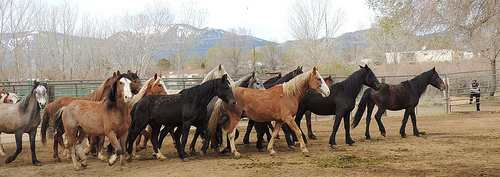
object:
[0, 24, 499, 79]
hills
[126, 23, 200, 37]
snow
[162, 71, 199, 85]
snow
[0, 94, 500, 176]
ground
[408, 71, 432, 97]
mane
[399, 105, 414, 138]
leg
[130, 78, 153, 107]
mane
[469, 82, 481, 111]
person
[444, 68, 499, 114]
fence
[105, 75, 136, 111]
mane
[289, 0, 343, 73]
trees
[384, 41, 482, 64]
building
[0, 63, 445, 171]
group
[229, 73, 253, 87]
mane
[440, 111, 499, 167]
grass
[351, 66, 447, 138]
front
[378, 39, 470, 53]
roof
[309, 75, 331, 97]
face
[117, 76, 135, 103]
face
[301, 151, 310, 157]
hoof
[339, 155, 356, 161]
patch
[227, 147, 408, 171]
green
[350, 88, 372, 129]
tail